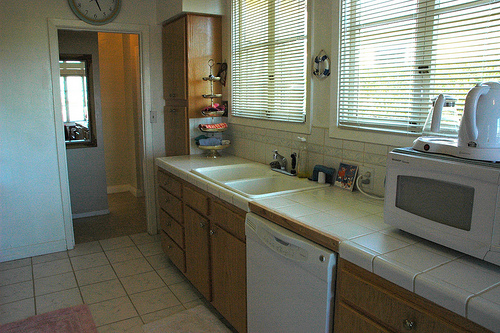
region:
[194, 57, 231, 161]
A stand with several trays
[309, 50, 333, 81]
A life preserver art piece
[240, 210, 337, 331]
A large white dishwasher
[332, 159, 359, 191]
A framed picture on the cabinet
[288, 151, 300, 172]
A black kitchen sink spray faucet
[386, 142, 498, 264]
A white microwave oven on the counter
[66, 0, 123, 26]
A circular clock over the door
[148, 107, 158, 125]
A light switch on the wall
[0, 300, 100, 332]
A light pink rug on the floor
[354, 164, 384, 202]
A cord plugged into a wall outlet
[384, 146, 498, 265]
white microwave counter over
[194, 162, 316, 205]
double kitchen porcelain sink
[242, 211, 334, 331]
recessed under counter dishwasher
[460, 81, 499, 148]
white electric kettle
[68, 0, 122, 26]
round wall clock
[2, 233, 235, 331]
tiled kitchen floor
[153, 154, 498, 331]
kitchen tile counter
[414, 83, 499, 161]
small kitchen appliance electric kettle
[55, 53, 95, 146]
rectangular mirror in hallway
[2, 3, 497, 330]
sunny kitchen with tile counter and tile floor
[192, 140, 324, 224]
kitchen sink is white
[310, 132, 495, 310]
microwave sitting on counter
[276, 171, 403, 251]
counter has white tile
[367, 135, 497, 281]
microwave on the counter is white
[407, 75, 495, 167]
white coffee maker on top of microwave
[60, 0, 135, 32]
white clock on wall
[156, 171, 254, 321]
bottom cabinets are brown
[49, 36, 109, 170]
mirror hanging on wall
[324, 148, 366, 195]
picture leaning on wall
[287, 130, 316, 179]
bottle next to sink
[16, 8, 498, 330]
the scene is in a kitchen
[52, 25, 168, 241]
the door is open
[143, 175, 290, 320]
the drawers are closed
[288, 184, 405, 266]
the shelf is white in colour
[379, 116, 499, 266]
the microwave is white in colour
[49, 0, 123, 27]
the clock is on the wall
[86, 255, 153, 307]
the floor is tiled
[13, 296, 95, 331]
a mat is on the floor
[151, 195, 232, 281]
the drawers are brown in colour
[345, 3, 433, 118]
the windows are closed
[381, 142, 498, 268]
the microwave on the counter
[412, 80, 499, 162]
the kettles on top of the microwave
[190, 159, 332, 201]
the double kitchen sink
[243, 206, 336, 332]
the white dishwasher under the sink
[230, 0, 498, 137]
the windows in the kitchen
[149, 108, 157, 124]
the light switch in the kitchen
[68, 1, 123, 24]
the clock hanging above the doorway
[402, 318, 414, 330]
the drawer pull on the drawer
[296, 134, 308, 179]
the plastic bottle of dishwash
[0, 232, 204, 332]
the tiles on the floor